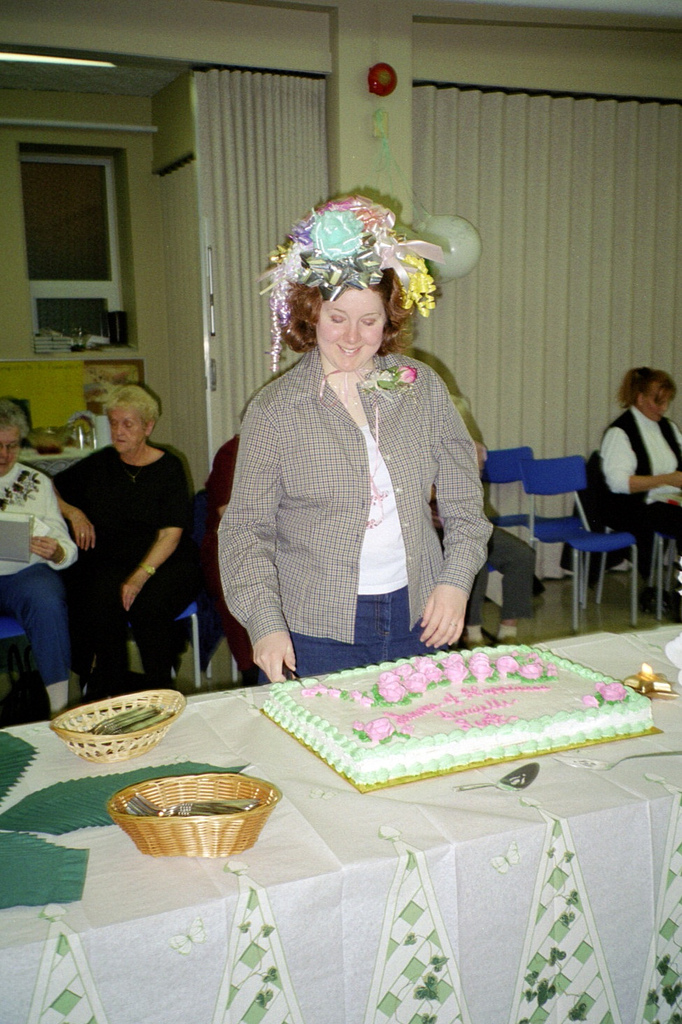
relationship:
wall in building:
[391, 36, 643, 98] [8, 4, 672, 1015]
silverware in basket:
[137, 778, 239, 828] [106, 772, 283, 859]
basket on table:
[106, 772, 283, 859] [137, 652, 485, 1021]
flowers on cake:
[386, 635, 510, 716] [299, 650, 537, 774]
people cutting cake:
[218, 184, 494, 683] [337, 649, 567, 820]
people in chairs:
[3, 358, 675, 712] [509, 352, 609, 578]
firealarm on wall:
[364, 44, 398, 92] [335, 110, 420, 180]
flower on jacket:
[364, 360, 412, 396] [254, 356, 493, 639]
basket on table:
[125, 752, 284, 885] [79, 657, 520, 945]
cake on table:
[263, 644, 653, 786] [133, 629, 629, 958]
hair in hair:
[258, 192, 443, 357] [285, 189, 435, 339]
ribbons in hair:
[294, 188, 393, 271] [285, 189, 435, 339]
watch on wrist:
[135, 558, 160, 577] [123, 555, 168, 603]